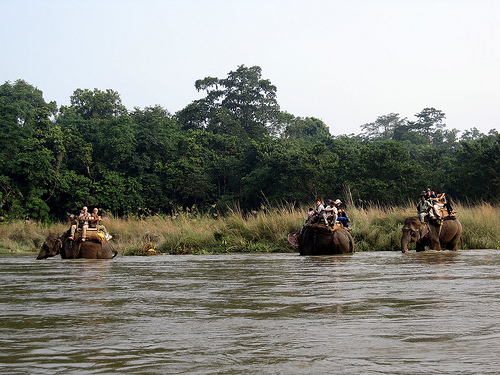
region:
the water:
[221, 288, 309, 345]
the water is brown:
[219, 290, 301, 351]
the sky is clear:
[333, 33, 405, 80]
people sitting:
[307, 197, 351, 224]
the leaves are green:
[198, 67, 292, 127]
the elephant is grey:
[396, 216, 473, 254]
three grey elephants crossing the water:
[53, 186, 468, 269]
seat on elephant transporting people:
[69, 203, 109, 245]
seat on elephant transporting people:
[301, 197, 347, 229]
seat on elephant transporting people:
[416, 189, 453, 222]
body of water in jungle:
[7, 249, 493, 369]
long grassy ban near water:
[13, 197, 499, 248]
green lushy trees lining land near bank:
[5, 64, 497, 214]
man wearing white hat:
[332, 198, 343, 206]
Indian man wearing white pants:
[418, 208, 430, 223]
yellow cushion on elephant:
[91, 233, 107, 244]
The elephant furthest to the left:
[33, 225, 118, 262]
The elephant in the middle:
[282, 217, 360, 259]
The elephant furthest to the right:
[396, 210, 463, 256]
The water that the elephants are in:
[1, 244, 498, 374]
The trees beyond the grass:
[0, 63, 497, 213]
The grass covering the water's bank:
[0, 185, 495, 257]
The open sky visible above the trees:
[0, 0, 497, 135]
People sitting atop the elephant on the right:
[415, 185, 457, 228]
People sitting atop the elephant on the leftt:
[65, 202, 116, 242]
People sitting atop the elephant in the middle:
[304, 193, 353, 235]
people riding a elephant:
[306, 189, 358, 242]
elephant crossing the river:
[19, 223, 124, 274]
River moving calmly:
[25, 263, 487, 347]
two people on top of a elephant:
[57, 200, 109, 234]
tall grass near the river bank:
[128, 193, 272, 253]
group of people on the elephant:
[411, 184, 458, 219]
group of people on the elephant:
[298, 192, 348, 234]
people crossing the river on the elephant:
[31, 188, 483, 248]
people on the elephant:
[28, 190, 470, 262]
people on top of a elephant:
[283, 181, 367, 266]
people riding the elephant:
[393, 184, 466, 259]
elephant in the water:
[396, 183, 468, 263]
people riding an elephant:
[413, 185, 456, 220]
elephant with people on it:
[289, 193, 357, 263]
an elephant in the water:
[283, 196, 363, 266]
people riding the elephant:
[299, 193, 355, 235]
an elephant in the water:
[31, 201, 119, 268]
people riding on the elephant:
[31, 201, 121, 266]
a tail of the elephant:
[111, 245, 119, 261]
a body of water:
[3, 268, 491, 373]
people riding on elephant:
[58, 202, 118, 257]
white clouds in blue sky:
[98, 20, 138, 45]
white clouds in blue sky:
[349, 39, 363, 54]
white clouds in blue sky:
[426, 26, 454, 48]